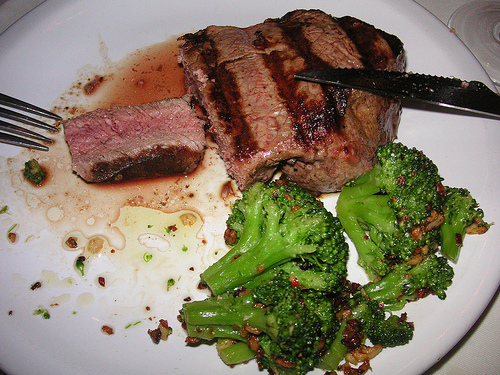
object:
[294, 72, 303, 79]
sharp tip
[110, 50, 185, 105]
soup remnants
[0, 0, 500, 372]
plate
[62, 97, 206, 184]
meat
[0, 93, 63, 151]
fork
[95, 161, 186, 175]
dark portion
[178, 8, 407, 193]
meat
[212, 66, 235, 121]
dark portion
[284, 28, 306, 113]
dark portion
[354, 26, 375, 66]
dark portion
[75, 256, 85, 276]
piece of food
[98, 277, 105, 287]
piece of food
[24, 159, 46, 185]
piece of food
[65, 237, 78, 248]
piece of food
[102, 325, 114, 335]
piece of food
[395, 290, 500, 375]
rim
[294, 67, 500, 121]
blade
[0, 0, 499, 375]
meal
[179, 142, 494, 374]
broccoli bunch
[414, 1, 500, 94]
glass